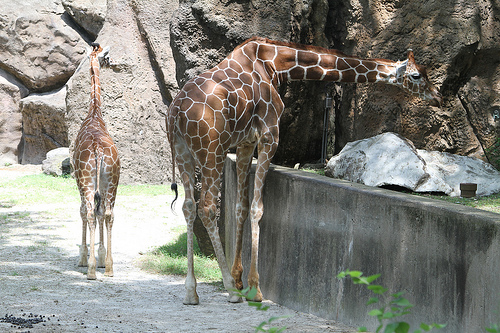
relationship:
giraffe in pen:
[165, 36, 444, 305] [2, 2, 497, 332]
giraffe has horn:
[165, 36, 444, 305] [408, 50, 416, 63]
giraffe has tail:
[165, 36, 444, 305] [167, 106, 182, 211]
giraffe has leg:
[165, 36, 444, 305] [248, 132, 278, 307]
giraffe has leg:
[165, 36, 444, 305] [185, 140, 241, 303]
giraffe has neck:
[165, 36, 444, 305] [260, 36, 399, 89]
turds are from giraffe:
[4, 311, 95, 332] [165, 36, 444, 305]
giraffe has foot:
[165, 36, 444, 305] [246, 291, 264, 303]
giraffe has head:
[165, 36, 444, 305] [398, 52, 443, 107]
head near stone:
[398, 52, 443, 107] [325, 133, 498, 198]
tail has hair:
[167, 106, 182, 211] [171, 185, 178, 209]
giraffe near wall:
[165, 36, 444, 305] [225, 150, 499, 330]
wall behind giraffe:
[225, 150, 499, 330] [165, 36, 444, 305]